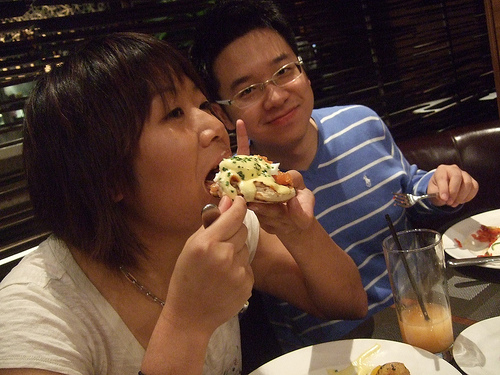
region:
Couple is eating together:
[3, 5, 479, 370]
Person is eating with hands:
[161, 148, 319, 310]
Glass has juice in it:
[385, 230, 455, 354]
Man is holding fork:
[193, 1, 475, 345]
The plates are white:
[235, 206, 499, 372]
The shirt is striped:
[231, 100, 461, 350]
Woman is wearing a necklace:
[104, 254, 167, 312]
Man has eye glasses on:
[205, 53, 306, 107]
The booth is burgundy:
[373, 113, 498, 245]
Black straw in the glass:
[381, 209, 433, 338]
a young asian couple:
[19, 10, 452, 329]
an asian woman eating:
[52, 52, 278, 272]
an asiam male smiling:
[171, 22, 422, 194]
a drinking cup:
[379, 231, 468, 341]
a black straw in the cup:
[378, 212, 435, 318]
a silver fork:
[392, 185, 447, 210]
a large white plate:
[256, 345, 441, 370]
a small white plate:
[455, 320, 495, 370]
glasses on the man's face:
[221, 39, 306, 111]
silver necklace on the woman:
[89, 242, 174, 307]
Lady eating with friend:
[2, 5, 372, 370]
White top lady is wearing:
[1, 208, 261, 373]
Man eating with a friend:
[215, 22, 481, 327]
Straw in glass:
[380, 206, 432, 322]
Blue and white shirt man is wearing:
[213, 98, 443, 319]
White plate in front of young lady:
[245, 334, 468, 373]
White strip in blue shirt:
[281, 170, 407, 220]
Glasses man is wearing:
[191, 52, 307, 108]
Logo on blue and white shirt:
[355, 170, 383, 195]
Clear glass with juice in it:
[381, 230, 454, 354]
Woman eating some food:
[18, 51, 299, 373]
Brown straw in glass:
[388, 213, 436, 338]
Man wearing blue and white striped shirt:
[208, 18, 452, 324]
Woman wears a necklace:
[108, 247, 205, 339]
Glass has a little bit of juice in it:
[367, 228, 466, 365]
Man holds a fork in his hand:
[376, 175, 483, 231]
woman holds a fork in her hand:
[191, 203, 271, 324]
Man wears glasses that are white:
[207, 53, 317, 114]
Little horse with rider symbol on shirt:
[357, 167, 380, 192]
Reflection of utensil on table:
[454, 275, 499, 299]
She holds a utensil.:
[202, 197, 251, 319]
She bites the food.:
[205, 153, 305, 221]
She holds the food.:
[251, 159, 322, 241]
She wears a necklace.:
[94, 253, 165, 308]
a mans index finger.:
[231, 118, 255, 158]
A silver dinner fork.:
[389, 187, 441, 210]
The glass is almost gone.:
[380, 224, 452, 350]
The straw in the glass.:
[382, 211, 430, 320]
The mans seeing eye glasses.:
[209, 49, 311, 111]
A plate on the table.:
[454, 303, 499, 373]